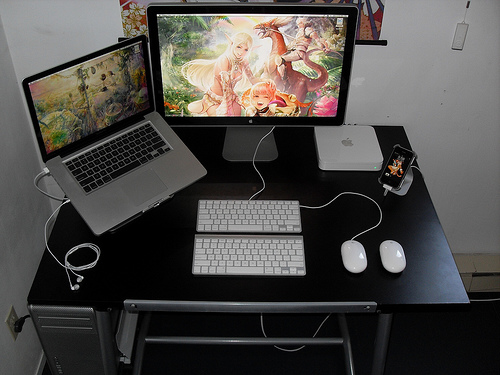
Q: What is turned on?
A: Computer screens.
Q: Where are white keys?
A: On two keyboards.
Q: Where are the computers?
A: On a desk.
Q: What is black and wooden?
A: The desk.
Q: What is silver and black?
A: Laptop computer.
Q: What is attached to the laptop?
A: Earphones.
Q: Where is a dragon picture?
A: On computer screen.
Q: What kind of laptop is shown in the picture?
A: A macbook.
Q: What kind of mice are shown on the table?
A: Apple mice.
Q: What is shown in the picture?
A: A computer and a laptop.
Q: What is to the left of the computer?
A: A laptop.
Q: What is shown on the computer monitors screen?
A: A fictional event.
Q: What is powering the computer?
A: The computer tower.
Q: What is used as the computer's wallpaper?
A: Fantasy scene.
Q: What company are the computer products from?
A: Apple computers.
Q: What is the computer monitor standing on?
A: A desk.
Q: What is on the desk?
A: Computers.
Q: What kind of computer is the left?
A: Laptop.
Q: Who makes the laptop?
A: Apple.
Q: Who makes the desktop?
A: Apple.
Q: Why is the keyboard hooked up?
A: To type.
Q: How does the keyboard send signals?
A: Through a corde.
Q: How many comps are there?
A: 2.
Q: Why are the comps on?
A: They are in use.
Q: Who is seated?
A: No one.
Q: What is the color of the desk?
A: Black.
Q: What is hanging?
A: A phone.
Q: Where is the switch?
A: On the wall.